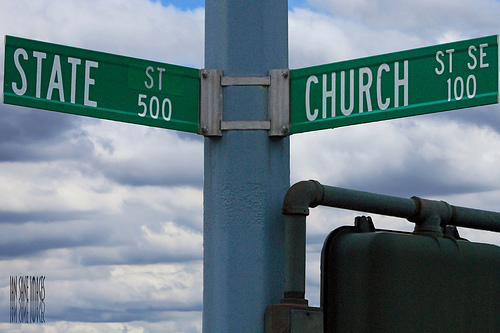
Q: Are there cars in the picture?
A: No, there are no cars.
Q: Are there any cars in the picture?
A: No, there are no cars.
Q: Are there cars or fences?
A: No, there are no cars or fences.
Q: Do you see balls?
A: No, there are no balls.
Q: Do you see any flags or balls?
A: No, there are no balls or flags.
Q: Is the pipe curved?
A: Yes, the pipe is curved.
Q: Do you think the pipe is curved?
A: Yes, the pipe is curved.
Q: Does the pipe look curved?
A: Yes, the pipe is curved.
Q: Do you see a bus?
A: No, there are no buses.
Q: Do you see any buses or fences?
A: No, there are no buses or fences.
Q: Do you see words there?
A: Yes, there are words.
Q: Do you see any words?
A: Yes, there are words.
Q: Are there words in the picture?
A: Yes, there are words.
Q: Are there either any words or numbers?
A: Yes, there are words.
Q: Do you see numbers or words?
A: Yes, there are words.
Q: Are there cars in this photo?
A: No, there are no cars.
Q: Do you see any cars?
A: No, there are no cars.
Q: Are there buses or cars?
A: No, there are no cars or buses.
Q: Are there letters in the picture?
A: Yes, there are letters.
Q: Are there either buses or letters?
A: Yes, there are letters.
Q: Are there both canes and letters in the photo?
A: No, there are letters but no canes.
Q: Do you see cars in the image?
A: No, there are no cars.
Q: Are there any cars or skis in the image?
A: No, there are no cars or skis.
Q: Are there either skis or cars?
A: No, there are no cars or skis.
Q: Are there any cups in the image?
A: No, there are no cups.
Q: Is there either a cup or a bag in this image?
A: No, there are no cups or bags.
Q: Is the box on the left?
A: No, the box is on the right of the image.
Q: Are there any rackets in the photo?
A: No, there are no rackets.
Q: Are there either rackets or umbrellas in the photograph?
A: No, there are no rackets or umbrellas.